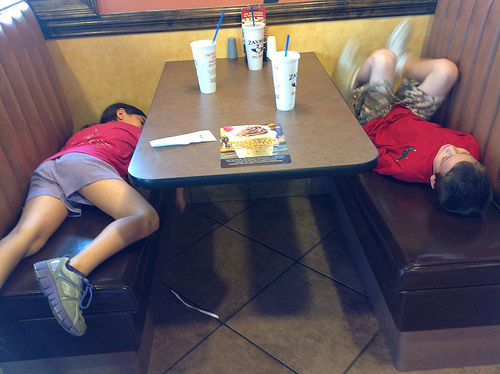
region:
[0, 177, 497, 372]
restaurant floor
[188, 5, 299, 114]
three fast food cups with straws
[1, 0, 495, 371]
two young boys sleeping in a fast food restaurant booth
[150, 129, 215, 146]
white paper napkin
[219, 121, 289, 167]
restaurant advertisement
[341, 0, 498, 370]
fast food restaurant booth bench seat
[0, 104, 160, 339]
sleeping boy wearing grey shorts red shirt and silver tennis shoes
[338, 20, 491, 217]
young boy sleeping in restaurant booth with feet on wall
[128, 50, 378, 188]
fast food restaurant table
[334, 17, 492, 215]
young boy wearing red shirt patterned shorts and white tennis shoes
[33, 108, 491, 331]
KIDS ARE LAYING ON THE BENCH SEATS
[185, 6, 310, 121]
THREE CUPS ARE ON THE TABLE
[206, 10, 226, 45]
STRAW IS BLUE IN COLOR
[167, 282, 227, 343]
STRAW WRAPPER IS ON THE FLOOR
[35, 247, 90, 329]
GIRL IS WEARING SNEAKERS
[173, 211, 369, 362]
FLOORING CONSIST OF BROWN TILE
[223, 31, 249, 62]
PEPPER SHAKER IS ON TABLE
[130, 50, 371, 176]
TABLE TOP IS BROWN IN COLOR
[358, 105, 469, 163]
BOY IS WEARING RED SHIRT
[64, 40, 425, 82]
BACK WALL IS YELLOW IN COLOR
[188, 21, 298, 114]
three zaxbys drink cups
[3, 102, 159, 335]
exhaused child layed down in booth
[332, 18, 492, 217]
moving feet to position on wall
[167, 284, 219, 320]
straw paper thrown carelessly on floor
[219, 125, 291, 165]
advertisment on table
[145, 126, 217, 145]
reciept laying on table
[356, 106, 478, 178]
boy wearing bright red shirt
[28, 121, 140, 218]
wearing red shirt and grey shorts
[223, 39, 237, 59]
pepper set against wall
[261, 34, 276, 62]
salt shaker near drink cup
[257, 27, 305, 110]
white paper cup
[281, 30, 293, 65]
blue straw in paper cup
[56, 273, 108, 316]
long laces in sneakers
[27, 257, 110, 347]
gray and silver sneakers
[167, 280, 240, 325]
white paper on tile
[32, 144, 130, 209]
pair of purple shorts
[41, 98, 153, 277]
girl sleeping on seat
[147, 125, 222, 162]
white bill on the table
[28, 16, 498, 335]
two kids asleep at mcdonalds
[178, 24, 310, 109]
three cups on a brown table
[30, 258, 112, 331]
purple and gray shoe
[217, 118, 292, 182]
menu laying on a brown table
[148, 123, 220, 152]
receipt laying on a table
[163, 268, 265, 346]
straw paper on a floor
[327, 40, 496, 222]
boy sleeping in a booth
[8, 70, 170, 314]
girl sleeping in a booth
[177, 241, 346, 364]
brown floor under the table